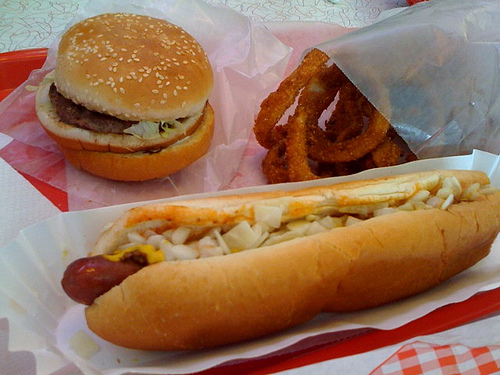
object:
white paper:
[0, 1, 497, 371]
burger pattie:
[45, 83, 140, 139]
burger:
[32, 10, 218, 180]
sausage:
[71, 110, 101, 130]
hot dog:
[62, 167, 499, 354]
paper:
[368, 340, 498, 374]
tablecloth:
[399, 329, 464, 359]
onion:
[224, 222, 256, 247]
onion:
[169, 224, 191, 243]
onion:
[301, 218, 323, 236]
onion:
[434, 188, 452, 200]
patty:
[39, 95, 154, 178]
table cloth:
[376, 341, 498, 373]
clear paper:
[215, 12, 285, 79]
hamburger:
[44, 27, 244, 212]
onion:
[247, 203, 284, 231]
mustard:
[97, 242, 167, 269]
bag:
[321, 30, 490, 163]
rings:
[245, 57, 482, 162]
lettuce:
[119, 114, 169, 149]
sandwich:
[40, 10, 217, 185]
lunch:
[42, 7, 497, 337]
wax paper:
[31, 3, 496, 202]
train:
[31, 11, 206, 186]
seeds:
[97, 43, 140, 73]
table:
[0, 2, 102, 44]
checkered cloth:
[368, 338, 498, 373]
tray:
[0, 2, 498, 374]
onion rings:
[252, 25, 455, 184]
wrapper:
[2, 0, 499, 215]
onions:
[125, 178, 495, 260]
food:
[84, 182, 465, 312]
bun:
[51, 12, 206, 118]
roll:
[85, 167, 498, 356]